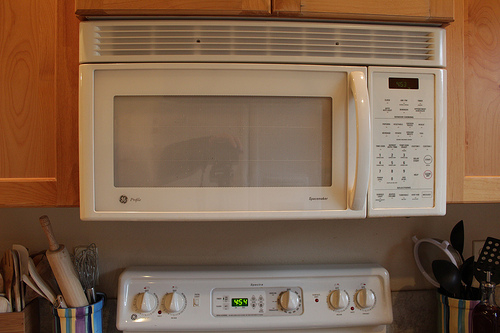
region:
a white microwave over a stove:
[39, 6, 469, 238]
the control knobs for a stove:
[109, 257, 404, 327]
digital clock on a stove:
[208, 287, 263, 324]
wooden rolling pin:
[42, 210, 83, 329]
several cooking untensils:
[406, 226, 496, 301]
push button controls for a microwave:
[350, 52, 450, 223]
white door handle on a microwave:
[341, 57, 383, 217]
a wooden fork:
[0, 243, 27, 316]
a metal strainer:
[413, 228, 468, 288]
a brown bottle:
[472, 271, 496, 331]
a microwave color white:
[53, 10, 463, 230]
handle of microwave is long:
[337, 64, 391, 219]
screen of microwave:
[381, 72, 423, 94]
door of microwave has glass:
[92, 64, 373, 222]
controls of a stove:
[107, 260, 407, 331]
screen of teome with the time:
[221, 285, 261, 315]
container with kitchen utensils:
[401, 217, 498, 325]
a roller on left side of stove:
[28, 205, 93, 315]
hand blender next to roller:
[72, 234, 112, 308]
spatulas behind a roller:
[17, 252, 64, 316]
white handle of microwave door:
[327, 72, 369, 216]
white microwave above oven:
[74, 13, 448, 222]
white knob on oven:
[131, 288, 162, 320]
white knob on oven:
[163, 292, 186, 320]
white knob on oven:
[279, 292, 307, 319]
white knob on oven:
[320, 285, 347, 310]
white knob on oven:
[356, 287, 378, 312]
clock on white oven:
[228, 293, 250, 308]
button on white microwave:
[422, 167, 433, 178]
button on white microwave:
[420, 154, 433, 164]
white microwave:
[72, 16, 459, 226]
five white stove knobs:
[117, 261, 394, 331]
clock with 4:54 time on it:
[219, 284, 272, 319]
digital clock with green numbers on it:
[222, 290, 266, 314]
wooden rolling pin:
[29, 210, 110, 323]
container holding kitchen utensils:
[15, 215, 109, 329]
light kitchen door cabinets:
[8, 49, 86, 216]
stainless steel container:
[432, 277, 494, 331]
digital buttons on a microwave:
[374, 71, 442, 211]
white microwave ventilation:
[76, 9, 455, 69]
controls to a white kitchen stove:
[116, 266, 400, 329]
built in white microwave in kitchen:
[75, 19, 459, 222]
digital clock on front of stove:
[228, 292, 258, 311]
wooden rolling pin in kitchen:
[34, 209, 91, 308]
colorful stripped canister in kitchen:
[43, 295, 102, 332]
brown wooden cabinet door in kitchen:
[1, 8, 96, 243]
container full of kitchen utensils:
[413, 223, 498, 301]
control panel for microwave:
[376, 81, 441, 205]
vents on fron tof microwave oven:
[93, 20, 496, 69]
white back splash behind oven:
[123, 228, 406, 263]